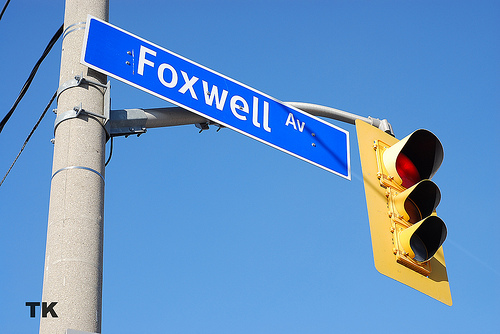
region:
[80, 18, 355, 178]
a blue street name sign with white letters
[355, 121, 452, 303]
a yellow framed traffic light set to red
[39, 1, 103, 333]
a steel pole holds the street name sign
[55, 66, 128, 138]
the mounting of the arm holding the traffic light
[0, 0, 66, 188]
utility lines runnint to the pole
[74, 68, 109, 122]
threaded screws hold steel bands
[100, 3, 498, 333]
crisp blue sky with no clouds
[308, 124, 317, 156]
the bolts that attach the street sign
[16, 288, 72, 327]
the name of the photographer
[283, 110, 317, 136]
the abbreviation for avenue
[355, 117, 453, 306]
Traffic control signal on pole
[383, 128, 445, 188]
Red light on traffic signal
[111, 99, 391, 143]
Metal traffic signal support pole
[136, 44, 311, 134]
Foxwell Av on street sign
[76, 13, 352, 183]
Street name identification sign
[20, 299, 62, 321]
Photograph owner identification mark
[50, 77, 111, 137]
Metal pole support brackets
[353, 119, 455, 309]
Yellow metal traffic signal housing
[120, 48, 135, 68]
Bolts on street identification sign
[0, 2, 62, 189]
Utility wires on metal pole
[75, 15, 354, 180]
a sign that says Foxwell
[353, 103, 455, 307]
a red stop light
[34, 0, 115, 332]
a tall concrete pole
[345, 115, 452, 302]
a yellow color stop light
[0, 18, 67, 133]
a black power cable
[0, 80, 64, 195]
a black power cable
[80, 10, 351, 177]
a blue street sign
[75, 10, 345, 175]
a blue street sign during the day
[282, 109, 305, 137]
the word Av on a sign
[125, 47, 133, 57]
a screw on a sign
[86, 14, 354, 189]
The street sign is blue.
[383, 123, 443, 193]
The street light is red.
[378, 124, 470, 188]
The traffic light is lit.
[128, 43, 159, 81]
The letter is white.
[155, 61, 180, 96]
The letter is white.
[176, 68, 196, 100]
The letter is white.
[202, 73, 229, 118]
The letter is white.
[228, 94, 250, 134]
The letter is white.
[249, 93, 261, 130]
The letter is white.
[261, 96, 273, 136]
The letter is white.